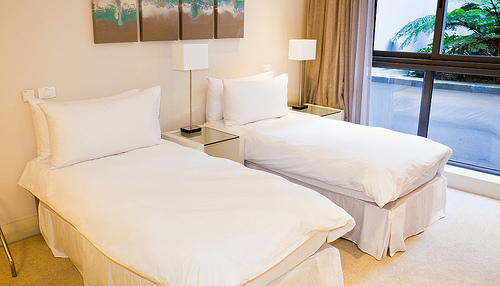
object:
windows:
[368, 1, 500, 178]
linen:
[19, 139, 355, 283]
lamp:
[169, 40, 211, 141]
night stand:
[165, 125, 242, 163]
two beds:
[15, 70, 452, 286]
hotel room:
[1, 0, 498, 282]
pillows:
[25, 83, 164, 171]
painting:
[89, 1, 246, 48]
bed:
[17, 83, 359, 282]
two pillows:
[200, 67, 290, 131]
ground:
[1, 184, 498, 284]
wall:
[2, 0, 309, 246]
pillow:
[38, 81, 162, 169]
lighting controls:
[18, 85, 61, 107]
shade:
[172, 43, 210, 74]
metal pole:
[185, 68, 195, 130]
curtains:
[304, 1, 374, 127]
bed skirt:
[242, 154, 449, 262]